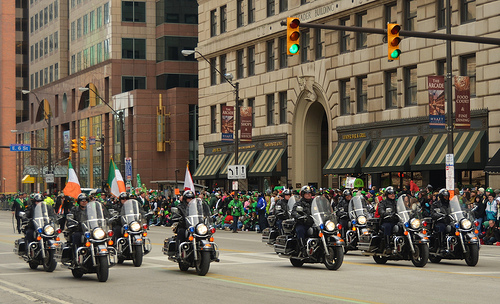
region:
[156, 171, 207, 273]
A person on a motorcycle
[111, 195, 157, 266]
A person on a motorcycle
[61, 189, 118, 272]
A person on a motorcycle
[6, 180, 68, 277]
A person on a motorcycle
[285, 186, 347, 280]
A person on a motorcycle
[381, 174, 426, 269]
A person on a motorcycle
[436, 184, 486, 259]
A person on a motorcycle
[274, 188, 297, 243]
A person on a motorcycle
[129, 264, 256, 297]
A grey tarmac road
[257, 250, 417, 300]
A grey tarmac road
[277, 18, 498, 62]
the traffic lights above the street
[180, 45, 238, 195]
the street lights on the sidewalk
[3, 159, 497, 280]
the large group of people in the city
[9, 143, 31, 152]
the blue street sign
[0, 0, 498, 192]
the buildings on the side of the street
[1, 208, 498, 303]
the street in front of the buildings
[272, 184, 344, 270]
the man riding a motorcycle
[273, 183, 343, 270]
the motorcycle the man is riding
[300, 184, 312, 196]
the helmet on the man's head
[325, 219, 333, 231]
the white light on the motorcycle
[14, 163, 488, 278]
several motorbikes on the road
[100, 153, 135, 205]
green, white, and orange flag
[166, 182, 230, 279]
person riding a motorcycle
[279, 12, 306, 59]
traffic light shining green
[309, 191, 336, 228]
windshield on the front of the bike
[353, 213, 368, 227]
light on the front of the bike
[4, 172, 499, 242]
crowd of people along the side of the street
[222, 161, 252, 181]
white and black sign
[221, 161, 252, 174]
three arrows on the sign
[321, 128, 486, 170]
three green and white striped awnings